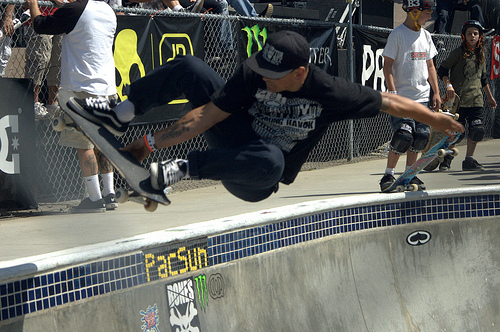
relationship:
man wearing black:
[81, 19, 467, 224] [309, 88, 343, 104]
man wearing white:
[81, 19, 467, 224] [114, 102, 130, 112]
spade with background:
[401, 225, 453, 266] [412, 232, 432, 235]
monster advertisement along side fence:
[149, 248, 238, 324] [158, 274, 197, 294]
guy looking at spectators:
[33, 7, 120, 209] [5, 7, 264, 165]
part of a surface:
[262, 250, 333, 319] [237, 239, 460, 327]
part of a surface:
[278, 249, 378, 319] [234, 226, 435, 330]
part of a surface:
[273, 259, 363, 308] [291, 237, 409, 314]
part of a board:
[94, 154, 158, 184] [111, 151, 171, 203]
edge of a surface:
[2, 176, 497, 273] [4, 121, 498, 328]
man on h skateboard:
[68, 31, 466, 203] [37, 90, 185, 249]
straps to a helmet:
[399, 2, 435, 58] [400, 0, 447, 33]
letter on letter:
[140, 249, 157, 283] [145, 246, 208, 282]